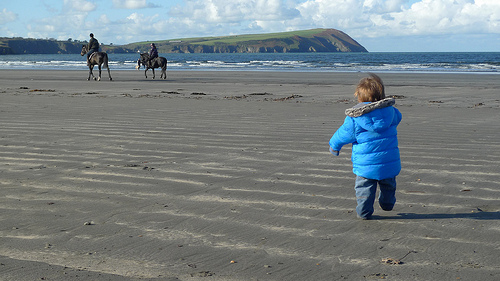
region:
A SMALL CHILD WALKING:
[325, 70, 402, 217]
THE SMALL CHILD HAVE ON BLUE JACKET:
[327, 96, 405, 178]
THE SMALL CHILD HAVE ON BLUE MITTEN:
[325, 143, 344, 160]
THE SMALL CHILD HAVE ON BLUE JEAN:
[355, 150, 400, 220]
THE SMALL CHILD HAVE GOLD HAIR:
[352, 73, 386, 100]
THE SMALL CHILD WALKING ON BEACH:
[0, 66, 499, 277]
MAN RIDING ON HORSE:
[129, 38, 174, 81]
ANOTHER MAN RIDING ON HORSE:
[74, 28, 116, 83]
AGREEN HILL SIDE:
[88, 26, 370, 54]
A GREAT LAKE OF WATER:
[0, 48, 499, 77]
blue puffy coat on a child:
[338, 103, 401, 188]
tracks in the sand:
[122, 151, 237, 253]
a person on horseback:
[79, 34, 111, 86]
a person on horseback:
[128, 42, 181, 88]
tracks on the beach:
[187, 79, 305, 127]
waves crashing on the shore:
[244, 49, 346, 82]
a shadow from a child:
[390, 185, 498, 259]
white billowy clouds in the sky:
[375, 0, 429, 40]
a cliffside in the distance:
[176, 26, 363, 58]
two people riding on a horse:
[78, 33, 170, 89]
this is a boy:
[313, 51, 415, 243]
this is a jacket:
[353, 118, 400, 159]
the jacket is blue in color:
[351, 129, 391, 166]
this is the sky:
[318, 0, 405, 33]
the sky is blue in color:
[26, 3, 51, 15]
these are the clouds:
[206, 3, 248, 23]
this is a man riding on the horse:
[81, 35, 120, 79]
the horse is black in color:
[98, 48, 114, 66]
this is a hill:
[229, 26, 305, 46]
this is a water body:
[396, 49, 446, 74]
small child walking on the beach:
[326, 72, 403, 220]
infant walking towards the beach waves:
[328, 73, 399, 216]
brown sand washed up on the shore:
[1, 71, 498, 278]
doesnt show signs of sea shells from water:
[1, 70, 498, 277]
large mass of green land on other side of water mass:
[0, 26, 370, 54]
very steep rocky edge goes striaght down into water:
[174, 31, 353, 55]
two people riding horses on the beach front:
[80, 33, 167, 83]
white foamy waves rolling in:
[0, 57, 499, 72]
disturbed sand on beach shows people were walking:
[1, 83, 496, 113]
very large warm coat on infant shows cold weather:
[329, 95, 404, 182]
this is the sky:
[14, 5, 35, 13]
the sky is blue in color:
[105, 3, 120, 16]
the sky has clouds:
[253, 6, 339, 24]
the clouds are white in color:
[238, 3, 309, 18]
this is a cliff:
[268, 23, 362, 50]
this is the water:
[382, 50, 442, 60]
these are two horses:
[82, 50, 168, 81]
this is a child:
[322, 69, 417, 213]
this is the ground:
[79, 184, 199, 239]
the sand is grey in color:
[143, 179, 280, 245]